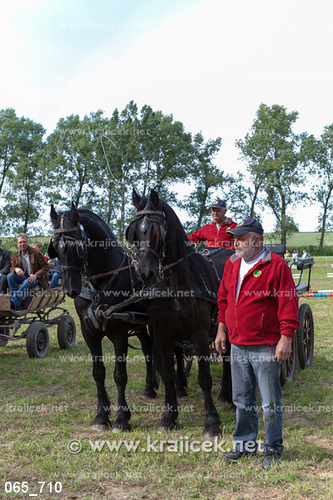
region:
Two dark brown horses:
[48, 189, 227, 434]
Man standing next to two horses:
[212, 217, 306, 465]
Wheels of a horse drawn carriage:
[281, 303, 320, 381]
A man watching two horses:
[9, 229, 53, 307]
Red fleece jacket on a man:
[209, 252, 302, 341]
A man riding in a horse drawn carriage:
[187, 197, 240, 246]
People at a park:
[283, 248, 312, 263]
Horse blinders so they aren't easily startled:
[152, 217, 170, 244]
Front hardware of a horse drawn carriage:
[81, 292, 152, 336]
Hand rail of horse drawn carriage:
[293, 256, 316, 295]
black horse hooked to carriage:
[119, 181, 235, 394]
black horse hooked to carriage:
[36, 195, 143, 453]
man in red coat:
[219, 221, 307, 481]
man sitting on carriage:
[182, 189, 309, 390]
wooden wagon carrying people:
[0, 222, 83, 371]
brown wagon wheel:
[293, 303, 326, 378]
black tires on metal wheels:
[19, 318, 84, 360]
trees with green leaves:
[244, 102, 320, 272]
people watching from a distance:
[283, 240, 324, 276]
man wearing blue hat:
[202, 192, 230, 230]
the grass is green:
[13, 379, 314, 478]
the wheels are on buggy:
[15, 315, 72, 346]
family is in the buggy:
[0, 245, 58, 306]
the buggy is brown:
[1, 293, 63, 308]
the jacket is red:
[224, 258, 281, 343]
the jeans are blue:
[228, 345, 282, 441]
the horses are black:
[55, 213, 222, 440]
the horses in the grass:
[49, 234, 226, 497]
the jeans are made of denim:
[229, 342, 284, 451]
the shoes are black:
[225, 446, 277, 467]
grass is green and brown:
[13, 381, 134, 497]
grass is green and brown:
[53, 412, 276, 494]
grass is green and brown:
[28, 427, 175, 498]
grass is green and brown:
[16, 430, 96, 498]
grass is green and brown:
[63, 468, 114, 491]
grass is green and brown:
[161, 463, 210, 477]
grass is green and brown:
[298, 427, 326, 467]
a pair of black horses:
[43, 186, 233, 440]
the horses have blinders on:
[46, 184, 172, 294]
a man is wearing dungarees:
[214, 217, 297, 449]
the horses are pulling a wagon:
[41, 181, 315, 427]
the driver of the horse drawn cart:
[178, 196, 241, 261]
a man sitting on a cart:
[3, 230, 73, 360]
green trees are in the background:
[0, 107, 330, 253]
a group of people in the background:
[281, 244, 315, 263]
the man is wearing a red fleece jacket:
[210, 219, 297, 365]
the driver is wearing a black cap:
[188, 197, 239, 251]